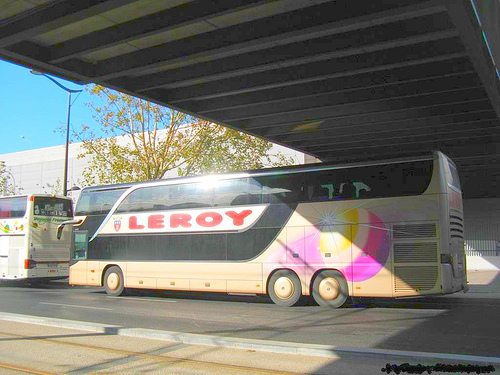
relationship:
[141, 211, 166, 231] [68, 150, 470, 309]
letter on bus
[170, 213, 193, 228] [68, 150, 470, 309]
letter on bus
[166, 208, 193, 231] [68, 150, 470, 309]
letter on bus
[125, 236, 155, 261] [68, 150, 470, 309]
bottom window of bus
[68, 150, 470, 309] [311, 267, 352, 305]
bus has tire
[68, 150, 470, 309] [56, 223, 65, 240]
bus has mirror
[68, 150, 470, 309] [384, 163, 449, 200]
bus has window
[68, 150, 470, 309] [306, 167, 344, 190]
bus has window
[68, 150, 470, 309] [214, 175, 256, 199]
bus has window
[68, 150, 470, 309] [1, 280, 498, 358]
bus on street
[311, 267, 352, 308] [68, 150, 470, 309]
tire on bus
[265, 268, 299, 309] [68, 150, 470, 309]
tire on bus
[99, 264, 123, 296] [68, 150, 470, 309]
tire on bus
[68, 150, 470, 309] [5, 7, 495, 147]
bus under freeway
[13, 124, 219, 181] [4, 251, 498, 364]
building by freeway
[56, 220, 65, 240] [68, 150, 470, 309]
mirror on bus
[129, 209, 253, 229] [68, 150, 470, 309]
logo on bus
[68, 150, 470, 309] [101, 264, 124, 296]
bus has tire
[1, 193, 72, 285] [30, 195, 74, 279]
decker bus seen back